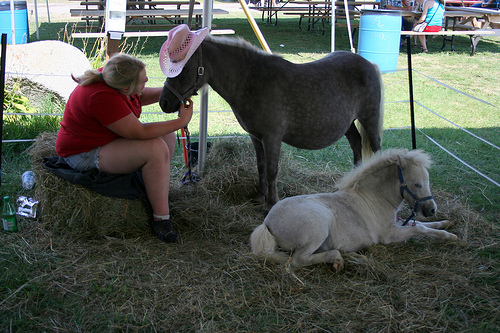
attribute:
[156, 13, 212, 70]
hat — pink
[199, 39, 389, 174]
horse — brown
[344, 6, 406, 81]
trash can — blue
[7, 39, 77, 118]
rock — huge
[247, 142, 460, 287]
pony — small, white, laying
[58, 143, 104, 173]
shorts — blue, jean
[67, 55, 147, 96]
hair — blonde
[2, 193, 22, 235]
bottle — green, plastic, beverage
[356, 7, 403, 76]
trashcan — green, metal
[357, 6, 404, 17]
bag — black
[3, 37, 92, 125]
boulder — large, white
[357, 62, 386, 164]
tail — long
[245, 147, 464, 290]
horse — white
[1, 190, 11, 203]
top — screw off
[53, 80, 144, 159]
tshirt — red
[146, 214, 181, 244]
shoes — black, tennis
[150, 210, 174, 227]
socks — white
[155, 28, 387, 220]
horse — brown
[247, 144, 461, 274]
horse — white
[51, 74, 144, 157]
shirt — red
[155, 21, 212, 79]
hat — pink